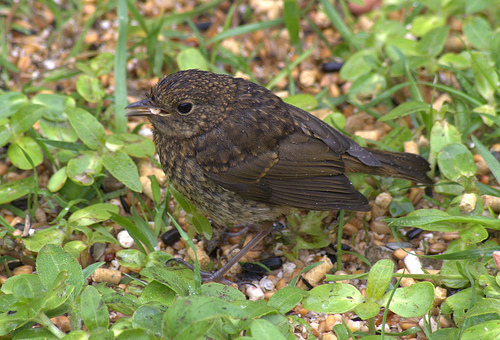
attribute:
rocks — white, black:
[10, 21, 84, 108]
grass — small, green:
[345, 23, 490, 87]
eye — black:
[178, 95, 194, 116]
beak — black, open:
[126, 87, 159, 124]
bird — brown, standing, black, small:
[127, 64, 365, 239]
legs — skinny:
[169, 223, 274, 278]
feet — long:
[143, 257, 230, 290]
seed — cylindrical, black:
[237, 252, 339, 300]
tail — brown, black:
[348, 150, 437, 194]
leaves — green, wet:
[69, 101, 131, 179]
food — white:
[240, 251, 433, 305]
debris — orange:
[21, 17, 98, 76]